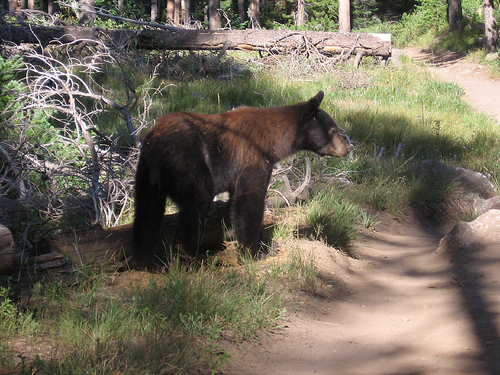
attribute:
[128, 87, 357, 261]
bear — ferocious, brown, strong, dark, mighty, heavy, dangerous, looking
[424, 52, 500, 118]
road — unpaved, narrow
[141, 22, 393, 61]
tree trunk — long, cut, gray, large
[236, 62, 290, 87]
grass — green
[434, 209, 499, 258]
stone — big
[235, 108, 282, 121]
fur — brown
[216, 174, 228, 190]
fur — black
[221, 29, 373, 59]
tree — dead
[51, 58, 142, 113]
branches — dead, dry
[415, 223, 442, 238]
dirt — brown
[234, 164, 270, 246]
leg — wide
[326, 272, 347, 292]
stones — small